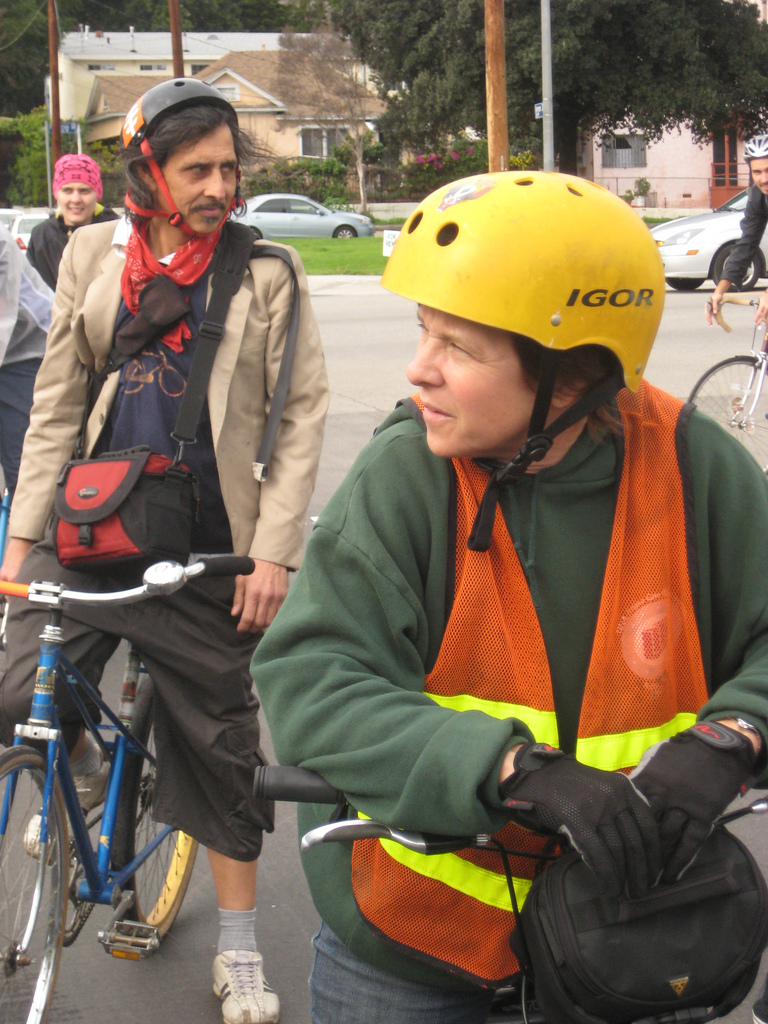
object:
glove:
[497, 739, 664, 898]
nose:
[404, 319, 444, 389]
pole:
[483, 2, 510, 173]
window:
[601, 133, 644, 168]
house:
[591, 113, 751, 212]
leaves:
[634, 6, 652, 25]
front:
[649, 206, 764, 291]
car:
[649, 183, 768, 292]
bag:
[54, 443, 198, 578]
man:
[250, 159, 768, 1023]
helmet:
[375, 167, 672, 393]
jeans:
[308, 914, 506, 1024]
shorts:
[0, 525, 273, 869]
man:
[0, 79, 334, 1018]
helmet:
[120, 73, 241, 153]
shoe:
[208, 940, 282, 1024]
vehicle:
[229, 191, 377, 239]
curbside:
[304, 265, 385, 282]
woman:
[24, 146, 121, 293]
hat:
[52, 152, 102, 200]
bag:
[505, 805, 768, 1022]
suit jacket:
[6, 214, 333, 573]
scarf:
[119, 219, 220, 355]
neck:
[147, 219, 198, 258]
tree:
[320, 0, 764, 178]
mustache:
[191, 199, 227, 212]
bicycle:
[0, 554, 258, 1021]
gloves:
[628, 715, 758, 882]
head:
[405, 222, 619, 471]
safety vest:
[346, 378, 710, 983]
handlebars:
[301, 818, 490, 856]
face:
[135, 119, 238, 235]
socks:
[217, 906, 258, 953]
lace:
[224, 959, 261, 1012]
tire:
[0, 739, 75, 1024]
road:
[0, 388, 305, 948]